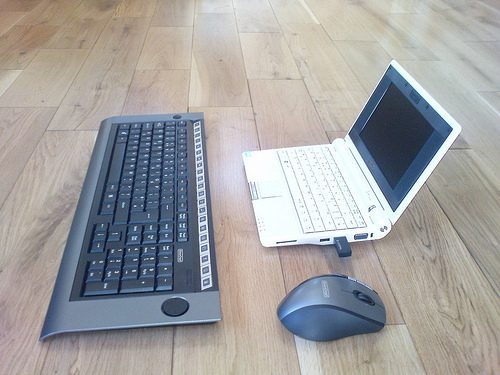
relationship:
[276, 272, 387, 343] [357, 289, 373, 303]
mouse has wheel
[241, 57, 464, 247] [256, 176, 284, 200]
computer has trackpad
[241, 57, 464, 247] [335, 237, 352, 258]
computer has usb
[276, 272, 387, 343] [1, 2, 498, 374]
mouse on floor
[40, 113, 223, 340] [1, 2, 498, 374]
keyboard on floor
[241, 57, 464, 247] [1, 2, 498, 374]
computer on floor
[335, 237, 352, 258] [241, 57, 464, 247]
usb in computer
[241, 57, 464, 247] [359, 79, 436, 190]
computer has screen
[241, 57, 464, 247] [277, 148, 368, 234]
computer has keyboard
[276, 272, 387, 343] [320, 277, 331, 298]
mouse has logo